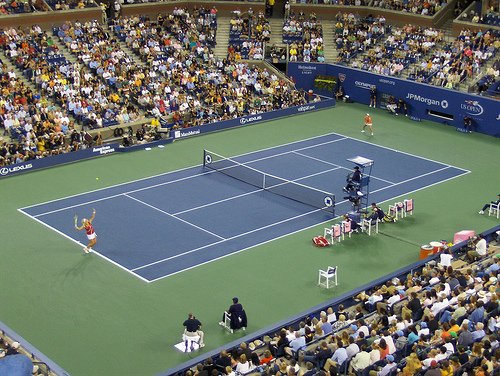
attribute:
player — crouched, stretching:
[73, 212, 102, 257]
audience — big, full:
[0, 2, 499, 176]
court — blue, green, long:
[18, 130, 472, 286]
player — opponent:
[363, 113, 375, 140]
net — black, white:
[200, 149, 341, 215]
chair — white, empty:
[319, 265, 340, 290]